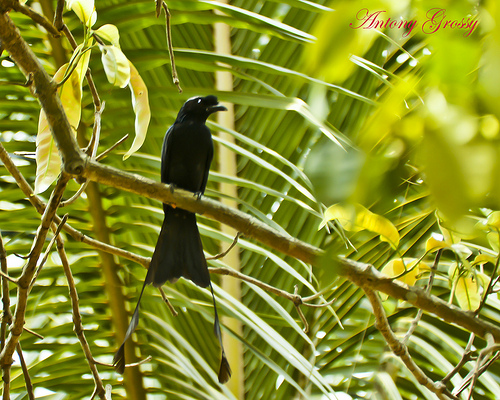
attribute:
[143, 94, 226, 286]
bird — black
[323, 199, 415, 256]
leaves — thin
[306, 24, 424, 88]
leaves — thin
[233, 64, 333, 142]
leaves — thin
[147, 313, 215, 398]
leaves — thin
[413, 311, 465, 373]
leaves — thin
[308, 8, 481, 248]
leaves — blurry